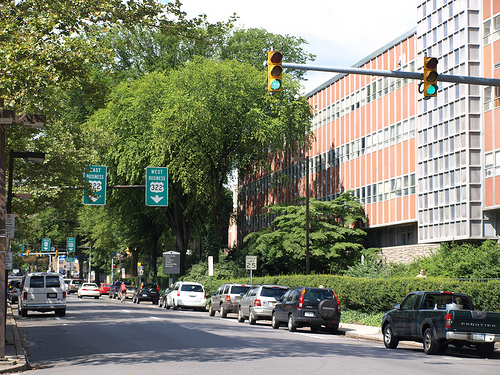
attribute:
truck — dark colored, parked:
[380, 290, 500, 357]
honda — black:
[271, 286, 342, 337]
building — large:
[236, 0, 497, 265]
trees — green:
[83, 56, 316, 275]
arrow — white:
[149, 193, 163, 204]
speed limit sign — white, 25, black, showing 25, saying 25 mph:
[244, 252, 259, 273]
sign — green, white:
[143, 166, 171, 210]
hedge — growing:
[199, 273, 498, 326]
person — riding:
[117, 280, 127, 302]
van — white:
[20, 273, 69, 318]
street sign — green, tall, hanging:
[267, 51, 289, 96]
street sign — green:
[423, 57, 440, 101]